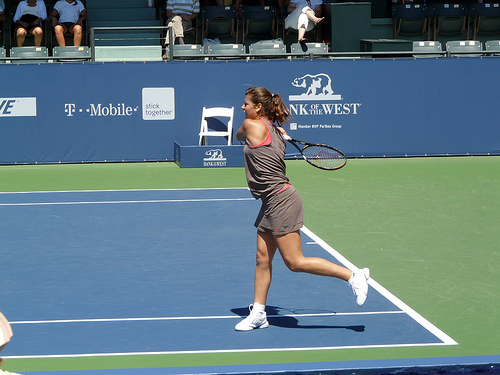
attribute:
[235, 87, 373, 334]
woman — playing, ready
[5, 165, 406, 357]
court — tennis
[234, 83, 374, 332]
tennis player — female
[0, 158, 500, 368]
tennis court — blue, hard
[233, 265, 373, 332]
shoes — tennis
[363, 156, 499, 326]
court — tennis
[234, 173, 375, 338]
girl — wearing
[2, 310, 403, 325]
line — solid, white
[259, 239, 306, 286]
knees — two people's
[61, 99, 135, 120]
logo — T-Mobile's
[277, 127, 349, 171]
racket — tennis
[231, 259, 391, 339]
shoes — white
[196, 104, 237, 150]
chair — white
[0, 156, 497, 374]
court — tennis